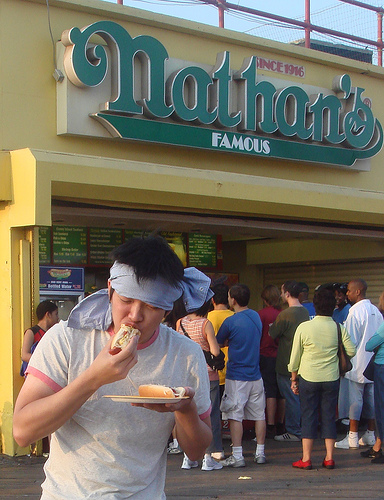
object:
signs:
[38, 220, 48, 263]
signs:
[87, 223, 125, 267]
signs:
[124, 225, 153, 243]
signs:
[184, 231, 219, 268]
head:
[188, 295, 214, 315]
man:
[10, 230, 214, 492]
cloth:
[63, 259, 212, 332]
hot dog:
[48, 266, 72, 279]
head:
[346, 277, 367, 301]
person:
[334, 279, 383, 451]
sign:
[61, 17, 384, 169]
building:
[0, 0, 382, 456]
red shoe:
[292, 458, 311, 469]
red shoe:
[322, 458, 335, 469]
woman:
[285, 283, 356, 469]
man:
[216, 281, 269, 467]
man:
[20, 300, 60, 374]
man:
[333, 275, 381, 452]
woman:
[331, 279, 350, 322]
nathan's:
[1, 0, 382, 462]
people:
[10, 239, 214, 496]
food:
[138, 384, 184, 401]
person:
[10, 240, 210, 500]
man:
[220, 285, 266, 467]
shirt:
[215, 305, 265, 379]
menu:
[38, 220, 223, 270]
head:
[105, 238, 183, 343]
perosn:
[17, 295, 59, 378]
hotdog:
[109, 324, 135, 353]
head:
[36, 298, 59, 328]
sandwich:
[137, 385, 185, 396]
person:
[287, 283, 354, 468]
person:
[217, 279, 269, 469]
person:
[176, 300, 222, 471]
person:
[207, 285, 248, 459]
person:
[359, 290, 382, 460]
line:
[159, 293, 382, 468]